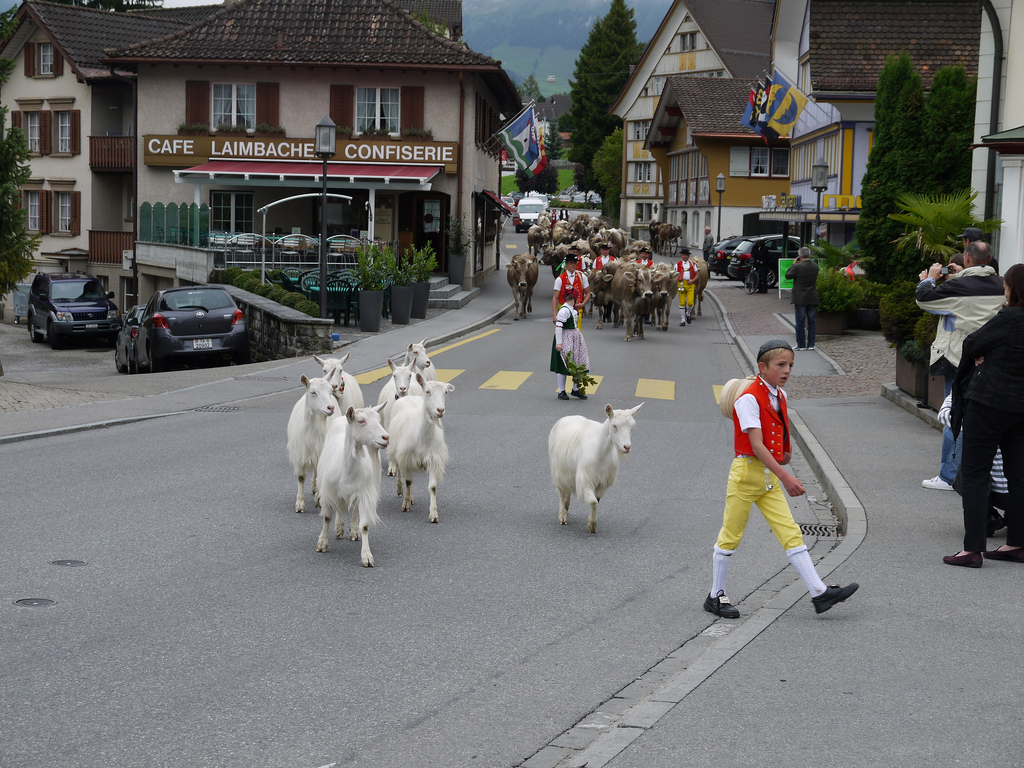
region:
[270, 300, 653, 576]
goats on the street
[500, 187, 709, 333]
Cattle on the street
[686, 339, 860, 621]
Red and yellow clothing on the boy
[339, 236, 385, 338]
Potted plant on the sidewalk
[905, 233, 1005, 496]
Man taking a picture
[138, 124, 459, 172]
Sign on the building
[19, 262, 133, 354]
Car parked on the street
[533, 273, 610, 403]
Little girl in a dress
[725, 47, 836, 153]
Flags on the building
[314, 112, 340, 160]
Light on top of the pole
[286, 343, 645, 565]
goats in the road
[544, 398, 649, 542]
the goat is white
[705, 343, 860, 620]
a kid is walking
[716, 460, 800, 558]
the pants are yellow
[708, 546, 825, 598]
the socks are white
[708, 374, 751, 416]
the hat is brown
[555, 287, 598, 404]
girl in the road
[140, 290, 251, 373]
the car is parked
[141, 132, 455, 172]
sign on the building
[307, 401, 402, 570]
a white fluffy goat walking on the street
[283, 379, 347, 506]
a white fluffy goat walking on the street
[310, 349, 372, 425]
a white fluffy goat walking on the street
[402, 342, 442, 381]
a white fluffy goat walking on the street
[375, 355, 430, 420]
a white fluffy goat walking on the street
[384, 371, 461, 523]
a white fluffy goat walking on the street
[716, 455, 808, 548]
a pair of yellow pants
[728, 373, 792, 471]
the red vest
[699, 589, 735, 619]
the black shoe of the boy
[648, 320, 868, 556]
kid walking on street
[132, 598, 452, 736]
street under the animals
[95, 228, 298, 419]
car next to the street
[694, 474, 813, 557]
yellow pants on kid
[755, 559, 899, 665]
shoeon the foot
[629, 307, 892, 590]
orange and yellow outfit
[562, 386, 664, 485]
head of the animal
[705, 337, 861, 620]
Brown haired boy in red vest and yellow pants.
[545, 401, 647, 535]
White goat behind a boy in red.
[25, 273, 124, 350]
Black parked suv down a brick road.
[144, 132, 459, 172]
Brown rectangle sign that says CAFE LAIMBACHE CONFISHERIE.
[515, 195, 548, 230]
White van down the road behind cattle.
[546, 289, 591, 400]
A girl in a green dress turned around.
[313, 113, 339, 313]
Black and clear light pole in between the words LAIMBACHE & CONFISERIE.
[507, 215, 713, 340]
Brown herd of cattle coming down a road.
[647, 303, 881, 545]
person wearing orange and yellow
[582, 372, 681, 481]
head of the animal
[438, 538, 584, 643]
street next to the animal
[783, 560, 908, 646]
foot of the person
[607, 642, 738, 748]
curb next to the street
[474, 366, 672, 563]
animal with white fur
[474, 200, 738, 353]
people and animals in distance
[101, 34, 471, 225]
words on the building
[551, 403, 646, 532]
white goat behind boy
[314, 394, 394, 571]
white goat behind boy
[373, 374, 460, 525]
white goat behind boy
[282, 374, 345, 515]
white goat behind boy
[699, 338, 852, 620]
boy walking in front of goat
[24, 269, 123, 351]
car parked on side of road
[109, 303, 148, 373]
car parked on side of road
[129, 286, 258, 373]
car parked on side of road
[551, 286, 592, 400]
girl walking behind goat